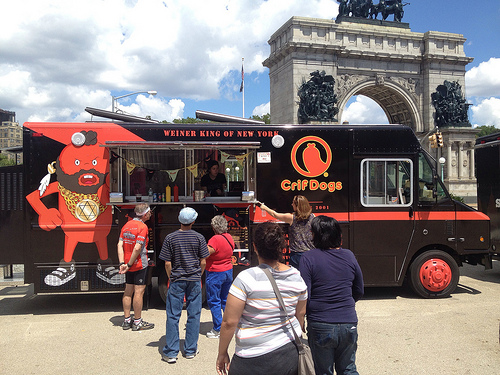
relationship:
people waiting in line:
[110, 185, 359, 365] [109, 195, 362, 369]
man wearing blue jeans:
[161, 202, 208, 367] [118, 254, 257, 356]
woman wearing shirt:
[216, 218, 314, 373] [229, 265, 308, 360]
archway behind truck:
[337, 74, 422, 131] [20, 105, 494, 307]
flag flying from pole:
[239, 71, 245, 94] [236, 58, 246, 116]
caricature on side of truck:
[25, 130, 126, 287] [21, 77, 493, 287]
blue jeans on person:
[157, 279, 204, 361] [158, 201, 213, 364]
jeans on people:
[304, 322, 358, 372] [117, 195, 366, 375]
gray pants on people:
[229, 340, 306, 372] [117, 195, 366, 375]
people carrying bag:
[117, 195, 366, 375] [263, 267, 315, 372]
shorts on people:
[120, 267, 149, 288] [117, 195, 366, 375]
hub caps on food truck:
[419, 258, 453, 292] [0, 106, 493, 310]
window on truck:
[107, 142, 256, 207] [20, 105, 494, 307]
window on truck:
[357, 156, 413, 206] [20, 105, 494, 307]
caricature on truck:
[26, 126, 131, 291] [20, 105, 494, 307]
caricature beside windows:
[25, 130, 126, 287] [96, 148, 267, 210]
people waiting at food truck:
[117, 195, 366, 375] [0, 106, 493, 310]